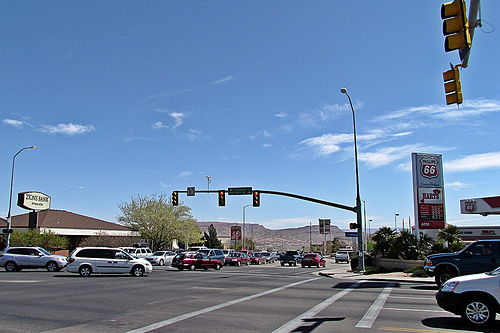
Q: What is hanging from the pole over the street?
A: Traffic lights.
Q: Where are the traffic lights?
A: On the pole.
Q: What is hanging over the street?
A: Traffic lights.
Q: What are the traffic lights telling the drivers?
A: Stop.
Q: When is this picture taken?
A: The daytime.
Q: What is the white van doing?
A: Turning down the street.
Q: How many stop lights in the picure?
A: Three.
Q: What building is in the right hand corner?
A: A gas station.